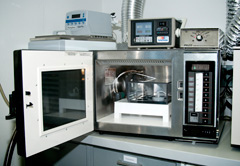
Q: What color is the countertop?
A: Gray.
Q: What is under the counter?
A: File drawers.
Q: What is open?
A: The microwave door.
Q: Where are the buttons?
A: On the side panel.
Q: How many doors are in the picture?
A: 1.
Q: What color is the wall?
A: White.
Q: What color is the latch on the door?
A: Black.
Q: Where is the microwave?
A: On the shelf.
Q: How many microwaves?
A: One.